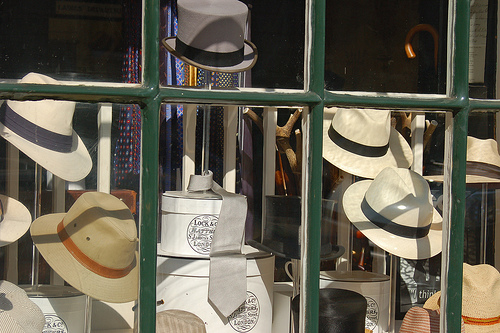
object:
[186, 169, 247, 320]
tie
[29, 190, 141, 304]
hat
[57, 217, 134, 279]
band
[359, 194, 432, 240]
band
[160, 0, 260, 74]
hat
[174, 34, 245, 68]
band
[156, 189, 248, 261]
boxes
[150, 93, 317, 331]
window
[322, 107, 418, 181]
hats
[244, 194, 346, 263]
hat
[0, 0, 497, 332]
display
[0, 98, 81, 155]
strip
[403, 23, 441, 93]
stick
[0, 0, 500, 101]
background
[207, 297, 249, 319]
end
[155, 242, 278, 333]
box